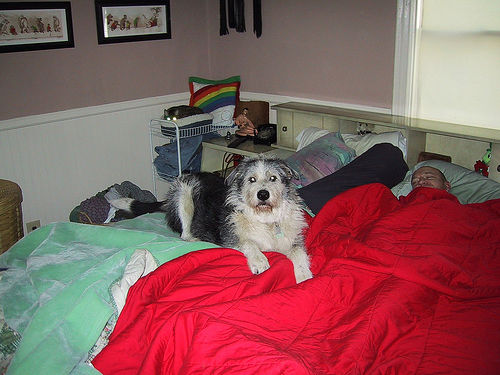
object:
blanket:
[90, 182, 496, 375]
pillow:
[188, 75, 241, 128]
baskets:
[151, 167, 197, 183]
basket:
[146, 119, 236, 137]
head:
[408, 166, 451, 194]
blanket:
[0, 210, 223, 375]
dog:
[165, 147, 318, 295]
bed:
[0, 100, 500, 375]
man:
[407, 165, 452, 193]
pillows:
[295, 122, 409, 162]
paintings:
[1, 7, 71, 46]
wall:
[0, 0, 400, 119]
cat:
[162, 103, 207, 116]